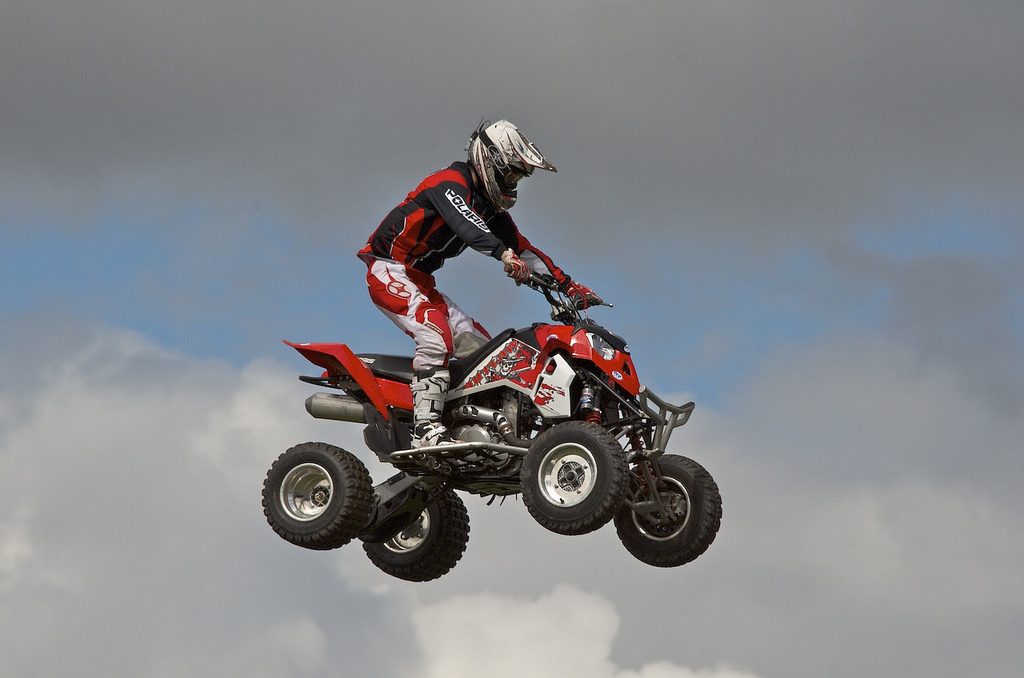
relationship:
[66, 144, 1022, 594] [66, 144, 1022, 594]
sky with clouds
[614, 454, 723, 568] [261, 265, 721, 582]
tire of object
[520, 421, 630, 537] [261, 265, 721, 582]
tire of object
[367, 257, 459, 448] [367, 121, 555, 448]
leg of man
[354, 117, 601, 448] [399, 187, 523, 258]
man wearing red black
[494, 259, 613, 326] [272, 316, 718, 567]
handlebars on vehicle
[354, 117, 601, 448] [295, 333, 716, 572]
man on four wheeler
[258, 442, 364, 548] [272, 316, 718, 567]
tire of vehicle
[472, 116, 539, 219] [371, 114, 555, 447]
helmet on person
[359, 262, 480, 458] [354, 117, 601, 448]
pants of man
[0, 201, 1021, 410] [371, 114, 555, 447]
sky above person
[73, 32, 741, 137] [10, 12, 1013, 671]
clouds in sky